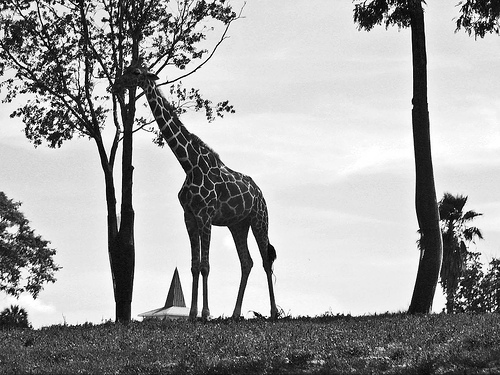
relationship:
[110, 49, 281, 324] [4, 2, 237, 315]
giraffe grazing tree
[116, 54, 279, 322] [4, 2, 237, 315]
giraffe grazing tree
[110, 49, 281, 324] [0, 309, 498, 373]
giraffe standing in grassy area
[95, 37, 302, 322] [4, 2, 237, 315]
giraffe eating leaves from tree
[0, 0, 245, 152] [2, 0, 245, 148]
leaves in branches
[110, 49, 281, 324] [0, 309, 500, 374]
giraffe on hill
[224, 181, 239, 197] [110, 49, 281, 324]
spots on side of giraffe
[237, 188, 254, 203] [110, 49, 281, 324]
spots on side of giraffe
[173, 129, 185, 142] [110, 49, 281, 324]
spots on side of giraffe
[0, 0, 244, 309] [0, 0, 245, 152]
tall tree with leaves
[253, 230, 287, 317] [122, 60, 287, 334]
leg of giraffe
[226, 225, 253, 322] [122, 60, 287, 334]
leg of giraffe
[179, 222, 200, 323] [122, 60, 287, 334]
leg of giraffe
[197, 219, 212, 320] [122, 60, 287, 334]
leg of giraffe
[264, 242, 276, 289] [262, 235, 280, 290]
tail on tail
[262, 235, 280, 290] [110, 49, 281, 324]
tail of giraffe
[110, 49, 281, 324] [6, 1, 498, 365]
giraffe in zoo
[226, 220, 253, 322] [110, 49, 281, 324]
leg of giraffe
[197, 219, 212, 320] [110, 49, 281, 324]
leg of giraffe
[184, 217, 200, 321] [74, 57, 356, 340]
leg of giraffe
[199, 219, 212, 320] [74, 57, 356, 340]
leg of giraffe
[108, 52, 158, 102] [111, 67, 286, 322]
head of giraffe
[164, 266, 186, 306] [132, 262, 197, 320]
pointy roof of building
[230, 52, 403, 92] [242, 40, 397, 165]
cloud in sky